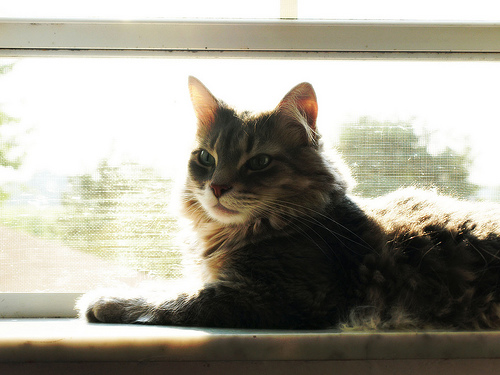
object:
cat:
[74, 74, 499, 331]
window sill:
[0, 316, 499, 360]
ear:
[275, 81, 319, 129]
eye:
[240, 152, 274, 171]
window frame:
[1, 19, 500, 60]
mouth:
[210, 200, 242, 214]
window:
[0, 0, 499, 320]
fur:
[392, 236, 499, 330]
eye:
[197, 147, 217, 169]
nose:
[208, 182, 232, 198]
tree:
[336, 115, 480, 199]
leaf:
[450, 158, 464, 167]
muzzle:
[208, 179, 243, 218]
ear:
[188, 75, 220, 124]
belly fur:
[336, 304, 415, 333]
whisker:
[261, 198, 369, 246]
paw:
[85, 297, 127, 322]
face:
[187, 129, 298, 224]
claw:
[91, 305, 94, 312]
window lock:
[278, 0, 299, 21]